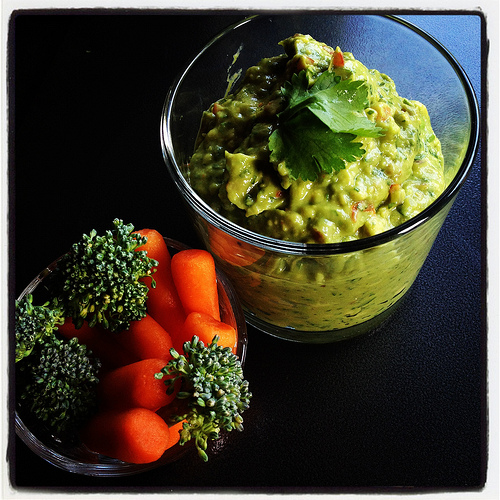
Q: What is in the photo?
A: Vegetables and guacamole.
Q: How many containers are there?
A: Two.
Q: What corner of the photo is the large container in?
A: Upper right.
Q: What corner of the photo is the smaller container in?
A: Lower left.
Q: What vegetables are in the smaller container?
A: Broccoli and carrots.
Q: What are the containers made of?
A: Glass.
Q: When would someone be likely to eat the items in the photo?
A: As an appetizer.